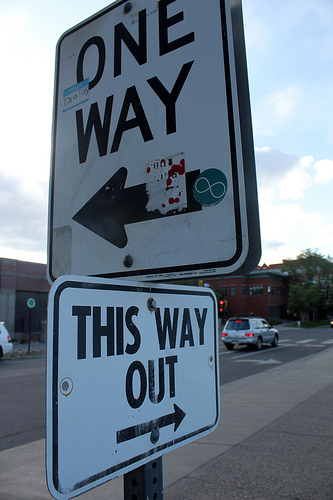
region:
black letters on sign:
[76, 18, 179, 134]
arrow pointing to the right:
[51, 176, 210, 236]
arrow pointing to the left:
[109, 403, 205, 439]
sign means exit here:
[69, 307, 204, 413]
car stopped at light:
[222, 323, 282, 357]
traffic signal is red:
[216, 294, 230, 318]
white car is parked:
[0, 319, 13, 365]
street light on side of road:
[26, 286, 35, 359]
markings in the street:
[235, 347, 293, 376]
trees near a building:
[292, 287, 331, 327]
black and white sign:
[32, 46, 238, 270]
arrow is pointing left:
[73, 142, 209, 247]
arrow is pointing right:
[119, 394, 188, 458]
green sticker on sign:
[186, 166, 223, 204]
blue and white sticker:
[58, 81, 90, 121]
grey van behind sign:
[203, 309, 284, 355]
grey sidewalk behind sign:
[176, 360, 332, 470]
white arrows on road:
[217, 342, 295, 374]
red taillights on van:
[215, 304, 249, 370]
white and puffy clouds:
[248, 128, 329, 245]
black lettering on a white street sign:
[66, 14, 197, 141]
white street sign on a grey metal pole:
[35, 276, 238, 487]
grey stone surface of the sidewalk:
[258, 445, 322, 488]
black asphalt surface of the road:
[7, 370, 38, 428]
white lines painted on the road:
[224, 353, 243, 367]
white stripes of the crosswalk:
[281, 329, 328, 348]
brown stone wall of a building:
[7, 261, 38, 289]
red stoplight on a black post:
[218, 294, 230, 325]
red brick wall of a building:
[236, 301, 260, 313]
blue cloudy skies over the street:
[278, 131, 313, 242]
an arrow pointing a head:
[162, 406, 186, 427]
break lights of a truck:
[223, 332, 228, 337]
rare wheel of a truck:
[256, 339, 260, 348]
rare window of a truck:
[230, 325, 245, 329]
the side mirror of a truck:
[267, 324, 272, 328]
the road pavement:
[271, 449, 311, 484]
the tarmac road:
[13, 380, 40, 400]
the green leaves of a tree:
[296, 286, 308, 297]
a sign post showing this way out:
[65, 295, 192, 408]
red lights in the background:
[220, 299, 226, 310]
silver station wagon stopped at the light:
[224, 317, 279, 349]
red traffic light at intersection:
[218, 299, 225, 314]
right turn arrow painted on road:
[238, 356, 281, 369]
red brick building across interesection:
[207, 275, 292, 325]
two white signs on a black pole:
[42, 2, 267, 499]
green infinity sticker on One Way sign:
[192, 163, 230, 207]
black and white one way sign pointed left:
[48, 12, 244, 275]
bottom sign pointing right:
[38, 279, 223, 487]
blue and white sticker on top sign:
[61, 77, 90, 110]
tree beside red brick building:
[284, 251, 331, 324]